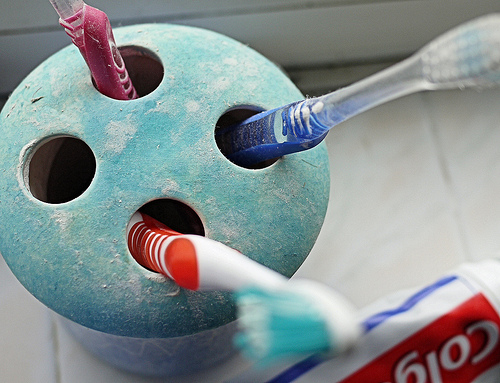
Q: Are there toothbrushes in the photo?
A: Yes, there is a toothbrush.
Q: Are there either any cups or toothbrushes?
A: Yes, there is a toothbrush.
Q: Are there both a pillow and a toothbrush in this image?
A: No, there is a toothbrush but no pillows.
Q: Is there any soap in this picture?
A: No, there are no soaps.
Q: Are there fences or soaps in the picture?
A: No, there are no soaps or fences.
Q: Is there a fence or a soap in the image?
A: No, there are no soaps or fences.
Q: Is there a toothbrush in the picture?
A: Yes, there is a toothbrush.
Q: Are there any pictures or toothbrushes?
A: Yes, there is a toothbrush.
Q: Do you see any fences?
A: No, there are no fences.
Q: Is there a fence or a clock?
A: No, there are no fences or clocks.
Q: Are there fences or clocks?
A: No, there are no fences or clocks.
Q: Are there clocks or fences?
A: No, there are no fences or clocks.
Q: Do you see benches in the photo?
A: No, there are no benches.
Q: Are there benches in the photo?
A: No, there are no benches.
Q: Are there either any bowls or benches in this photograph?
A: No, there are no benches or bowls.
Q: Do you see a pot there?
A: No, there are no pots.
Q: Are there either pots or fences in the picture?
A: No, there are no pots or fences.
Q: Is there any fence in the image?
A: No, there are no fences.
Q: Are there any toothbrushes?
A: Yes, there is a toothbrush.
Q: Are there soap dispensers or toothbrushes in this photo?
A: Yes, there is a toothbrush.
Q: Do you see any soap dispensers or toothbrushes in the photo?
A: Yes, there is a toothbrush.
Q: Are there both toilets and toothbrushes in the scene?
A: No, there is a toothbrush but no toilets.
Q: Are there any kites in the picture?
A: No, there are no kites.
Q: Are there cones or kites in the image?
A: No, there are no kites or cones.